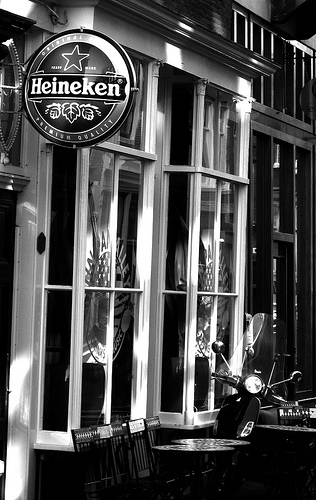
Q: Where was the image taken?
A: It was taken at the restaurant.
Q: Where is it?
A: This is at the restaurant.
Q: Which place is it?
A: It is a restaurant.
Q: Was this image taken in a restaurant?
A: Yes, it was taken in a restaurant.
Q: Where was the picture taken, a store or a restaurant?
A: It was taken at a restaurant.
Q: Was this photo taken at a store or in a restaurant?
A: It was taken at a restaurant.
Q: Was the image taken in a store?
A: No, the picture was taken in a restaurant.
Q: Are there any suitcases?
A: No, there are no suitcases.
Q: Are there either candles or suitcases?
A: No, there are no suitcases or candles.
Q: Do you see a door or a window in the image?
A: Yes, there is a window.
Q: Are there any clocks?
A: No, there are no clocks.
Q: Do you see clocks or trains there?
A: No, there are no clocks or trains.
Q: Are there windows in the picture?
A: Yes, there is a window.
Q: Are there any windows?
A: Yes, there is a window.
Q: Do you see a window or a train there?
A: Yes, there is a window.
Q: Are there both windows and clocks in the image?
A: No, there is a window but no clocks.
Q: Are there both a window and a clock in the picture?
A: No, there is a window but no clocks.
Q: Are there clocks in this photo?
A: No, there are no clocks.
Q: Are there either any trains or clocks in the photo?
A: No, there are no clocks or trains.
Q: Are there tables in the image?
A: Yes, there is a table.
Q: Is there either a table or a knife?
A: Yes, there is a table.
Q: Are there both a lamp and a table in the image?
A: No, there is a table but no lamps.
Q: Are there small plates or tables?
A: Yes, there is a small table.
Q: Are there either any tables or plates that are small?
A: Yes, the table is small.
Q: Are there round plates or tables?
A: Yes, there is a round table.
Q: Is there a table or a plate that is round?
A: Yes, the table is round.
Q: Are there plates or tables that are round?
A: Yes, the table is round.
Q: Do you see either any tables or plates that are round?
A: Yes, the table is round.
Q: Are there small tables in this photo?
A: Yes, there is a small table.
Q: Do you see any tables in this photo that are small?
A: Yes, there is a table that is small.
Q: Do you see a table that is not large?
A: Yes, there is a small table.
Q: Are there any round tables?
A: Yes, there is a round table.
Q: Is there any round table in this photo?
A: Yes, there is a round table.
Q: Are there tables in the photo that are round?
A: Yes, there is a table that is round.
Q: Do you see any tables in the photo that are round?
A: Yes, there is a table that is round.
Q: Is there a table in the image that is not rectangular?
A: Yes, there is a round table.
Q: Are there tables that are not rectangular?
A: Yes, there is a round table.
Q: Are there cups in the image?
A: No, there are no cups.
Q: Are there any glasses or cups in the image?
A: No, there are no cups or glasses.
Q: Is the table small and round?
A: Yes, the table is small and round.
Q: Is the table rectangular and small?
A: No, the table is small but round.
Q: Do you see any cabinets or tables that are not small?
A: No, there is a table but it is small.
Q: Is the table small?
A: Yes, the table is small.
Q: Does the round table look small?
A: Yes, the table is small.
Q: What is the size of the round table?
A: The table is small.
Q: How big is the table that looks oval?
A: The table is small.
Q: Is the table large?
A: No, the table is small.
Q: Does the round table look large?
A: No, the table is small.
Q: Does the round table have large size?
A: No, the table is small.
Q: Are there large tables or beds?
A: No, there is a table but it is small.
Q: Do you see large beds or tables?
A: No, there is a table but it is small.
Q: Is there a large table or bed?
A: No, there is a table but it is small.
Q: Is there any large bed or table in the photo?
A: No, there is a table but it is small.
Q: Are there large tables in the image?
A: No, there is a table but it is small.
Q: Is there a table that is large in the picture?
A: No, there is a table but it is small.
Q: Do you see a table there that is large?
A: No, there is a table but it is small.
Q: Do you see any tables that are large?
A: No, there is a table but it is small.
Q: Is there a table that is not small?
A: No, there is a table but it is small.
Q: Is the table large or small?
A: The table is small.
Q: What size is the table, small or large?
A: The table is small.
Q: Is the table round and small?
A: Yes, the table is round and small.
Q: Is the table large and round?
A: No, the table is round but small.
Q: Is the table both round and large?
A: No, the table is round but small.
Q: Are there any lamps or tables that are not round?
A: No, there is a table but it is round.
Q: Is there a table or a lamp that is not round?
A: No, there is a table but it is round.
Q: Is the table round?
A: Yes, the table is round.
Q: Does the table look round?
A: Yes, the table is round.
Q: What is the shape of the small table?
A: The table is round.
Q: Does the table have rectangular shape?
A: No, the table is round.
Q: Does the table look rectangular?
A: No, the table is round.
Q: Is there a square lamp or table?
A: No, there is a table but it is round.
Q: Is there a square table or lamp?
A: No, there is a table but it is round.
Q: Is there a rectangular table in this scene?
A: No, there is a table but it is round.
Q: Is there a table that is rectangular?
A: No, there is a table but it is round.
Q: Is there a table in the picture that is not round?
A: No, there is a table but it is round.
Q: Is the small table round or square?
A: The table is round.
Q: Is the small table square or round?
A: The table is round.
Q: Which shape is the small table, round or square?
A: The table is round.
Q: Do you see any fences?
A: No, there are no fences.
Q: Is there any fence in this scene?
A: No, there are no fences.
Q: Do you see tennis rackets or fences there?
A: No, there are no fences or tennis rackets.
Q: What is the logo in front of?
A: The logo is in front of the window.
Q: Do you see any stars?
A: Yes, there is a star.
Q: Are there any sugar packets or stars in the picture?
A: Yes, there is a star.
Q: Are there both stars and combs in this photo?
A: No, there is a star but no combs.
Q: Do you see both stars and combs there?
A: No, there is a star but no combs.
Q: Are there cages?
A: No, there are no cages.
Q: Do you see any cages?
A: No, there are no cages.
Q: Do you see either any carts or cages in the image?
A: No, there are no cages or carts.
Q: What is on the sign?
A: The star is on the sign.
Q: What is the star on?
A: The star is on the sign.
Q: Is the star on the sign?
A: Yes, the star is on the sign.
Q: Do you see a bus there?
A: No, there are no buses.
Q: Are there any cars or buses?
A: No, there are no buses or cars.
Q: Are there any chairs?
A: Yes, there is a chair.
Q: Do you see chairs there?
A: Yes, there is a chair.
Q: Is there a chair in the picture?
A: Yes, there is a chair.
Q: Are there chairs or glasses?
A: Yes, there is a chair.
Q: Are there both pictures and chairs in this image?
A: No, there is a chair but no pictures.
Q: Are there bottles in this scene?
A: No, there are no bottles.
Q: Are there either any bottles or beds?
A: No, there are no bottles or beds.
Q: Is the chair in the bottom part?
A: Yes, the chair is in the bottom of the image.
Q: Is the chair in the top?
A: No, the chair is in the bottom of the image.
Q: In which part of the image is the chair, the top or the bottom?
A: The chair is in the bottom of the image.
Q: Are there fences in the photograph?
A: No, there are no fences.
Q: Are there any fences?
A: No, there are no fences.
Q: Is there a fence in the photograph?
A: No, there are no fences.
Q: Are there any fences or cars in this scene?
A: No, there are no fences or cars.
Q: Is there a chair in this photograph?
A: Yes, there is a chair.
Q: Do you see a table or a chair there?
A: Yes, there is a chair.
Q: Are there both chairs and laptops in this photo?
A: No, there is a chair but no laptops.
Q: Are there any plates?
A: No, there are no plates.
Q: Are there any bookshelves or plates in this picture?
A: No, there are no plates or bookshelves.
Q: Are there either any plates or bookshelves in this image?
A: No, there are no plates or bookshelves.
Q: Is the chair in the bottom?
A: Yes, the chair is in the bottom of the image.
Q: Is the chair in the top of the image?
A: No, the chair is in the bottom of the image.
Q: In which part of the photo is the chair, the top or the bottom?
A: The chair is in the bottom of the image.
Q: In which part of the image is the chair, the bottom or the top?
A: The chair is in the bottom of the image.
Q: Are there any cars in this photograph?
A: No, there are no cars.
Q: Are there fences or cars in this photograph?
A: No, there are no cars or fences.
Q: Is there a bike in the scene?
A: Yes, there is a bike.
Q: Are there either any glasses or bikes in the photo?
A: Yes, there is a bike.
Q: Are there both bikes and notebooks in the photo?
A: No, there is a bike but no notebooks.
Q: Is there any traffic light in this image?
A: No, there are no traffic lights.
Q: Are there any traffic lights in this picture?
A: No, there are no traffic lights.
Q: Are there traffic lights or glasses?
A: No, there are no traffic lights or glasses.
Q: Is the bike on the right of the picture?
A: Yes, the bike is on the right of the image.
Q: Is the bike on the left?
A: No, the bike is on the right of the image.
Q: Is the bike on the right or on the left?
A: The bike is on the right of the image.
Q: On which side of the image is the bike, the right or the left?
A: The bike is on the right of the image.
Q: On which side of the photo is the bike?
A: The bike is on the right of the image.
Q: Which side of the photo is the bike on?
A: The bike is on the right of the image.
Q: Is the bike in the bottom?
A: Yes, the bike is in the bottom of the image.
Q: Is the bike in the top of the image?
A: No, the bike is in the bottom of the image.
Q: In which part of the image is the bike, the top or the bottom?
A: The bike is in the bottom of the image.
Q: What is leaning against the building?
A: The bike is leaning against the building.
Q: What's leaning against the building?
A: The bike is leaning against the building.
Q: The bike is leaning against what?
A: The bike is leaning against the building.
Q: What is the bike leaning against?
A: The bike is leaning against the building.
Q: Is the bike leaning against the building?
A: Yes, the bike is leaning against the building.